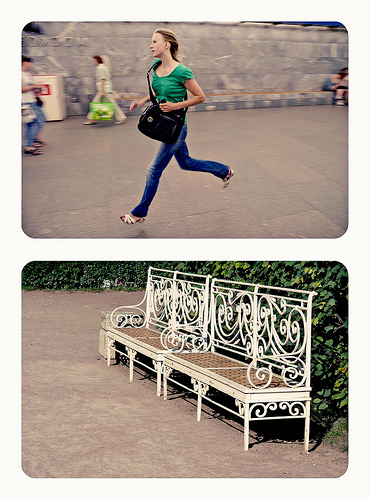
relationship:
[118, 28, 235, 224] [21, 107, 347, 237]
woman in street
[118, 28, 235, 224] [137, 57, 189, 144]
woman holding purse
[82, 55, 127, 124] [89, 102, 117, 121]
woman carrying bag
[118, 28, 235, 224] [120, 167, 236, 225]
woman wearing sandals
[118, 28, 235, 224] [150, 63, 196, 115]
woman wearing shirt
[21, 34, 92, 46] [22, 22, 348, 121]
logo on wall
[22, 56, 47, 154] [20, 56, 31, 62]
person wearing cap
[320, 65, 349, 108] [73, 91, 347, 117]
people on bench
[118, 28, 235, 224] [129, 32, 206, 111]
woman has skin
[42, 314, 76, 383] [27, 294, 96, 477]
part of floor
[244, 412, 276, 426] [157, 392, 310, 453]
part of stand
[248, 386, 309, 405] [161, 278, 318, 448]
edge of bench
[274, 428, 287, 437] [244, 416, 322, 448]
part of shade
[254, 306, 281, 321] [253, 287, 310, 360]
part of metal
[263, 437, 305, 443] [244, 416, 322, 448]
edge of shade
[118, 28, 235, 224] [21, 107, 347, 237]
woman down street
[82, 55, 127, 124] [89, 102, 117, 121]
woman with bag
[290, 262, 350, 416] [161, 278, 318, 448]
bushes in back of bench